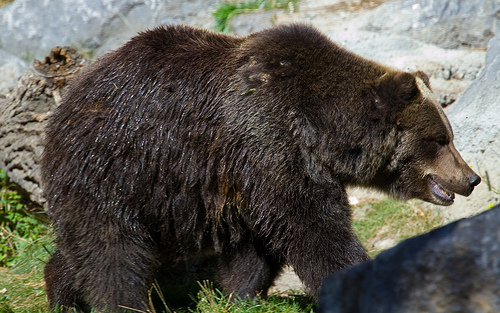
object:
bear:
[36, 20, 480, 312]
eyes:
[431, 132, 450, 145]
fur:
[99, 63, 307, 216]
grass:
[191, 292, 306, 313]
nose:
[469, 174, 481, 185]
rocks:
[0, 0, 497, 126]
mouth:
[426, 176, 466, 205]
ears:
[375, 72, 416, 102]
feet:
[78, 268, 161, 313]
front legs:
[277, 232, 384, 297]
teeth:
[434, 185, 451, 198]